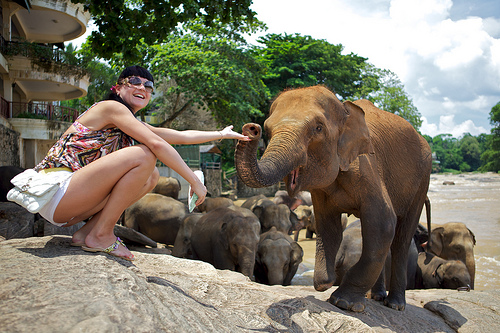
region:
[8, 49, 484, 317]
Woman getting close to an elephant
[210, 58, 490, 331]
Baby elephant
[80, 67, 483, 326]
Herd of elephants near water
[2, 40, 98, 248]
Building with a balcony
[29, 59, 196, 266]
Woman wearing sunglasses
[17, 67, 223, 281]
Woman wearing flip flops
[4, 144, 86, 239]
White purse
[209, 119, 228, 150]
Braclet on a woman's wrist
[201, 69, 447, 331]
Elephant walking on a rock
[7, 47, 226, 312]
Woman wearing white shorts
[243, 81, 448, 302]
brown elephant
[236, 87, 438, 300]
brown elephant touching young woman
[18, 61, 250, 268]
young woman touching brown elephant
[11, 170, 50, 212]
white purse worn by young woman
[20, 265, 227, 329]
gray rock by young woman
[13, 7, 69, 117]
balconies by river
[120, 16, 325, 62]
trees with green leaves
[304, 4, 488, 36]
white clouds against blue sky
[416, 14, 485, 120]
white clouds against blue sky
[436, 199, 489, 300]
brown elephants in river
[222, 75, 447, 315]
young elephant with older elephants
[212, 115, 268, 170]
hand stretched towards elephant's trunk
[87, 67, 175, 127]
woman is wearing sunglasses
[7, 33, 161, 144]
balconies of building behind woman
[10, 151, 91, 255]
matching white purse and shorts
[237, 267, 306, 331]
shadow cast of elephants trunk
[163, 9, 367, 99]
green tree tops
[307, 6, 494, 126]
big fluffy white clouds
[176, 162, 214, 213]
woman holding something in hands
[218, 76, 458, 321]
elephant playing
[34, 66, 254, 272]
a lady feeding a elephant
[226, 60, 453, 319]
an elephant eating from a lady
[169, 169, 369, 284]
a bunch of elephants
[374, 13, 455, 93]
a few clouds in the sky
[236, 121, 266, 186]
the nose of the elephant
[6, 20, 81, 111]
the building in the photo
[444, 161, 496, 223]
the river in the picture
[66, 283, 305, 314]
the rocks the lady is kneeling on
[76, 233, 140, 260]
the ladies feet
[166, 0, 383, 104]
trees that are in the photo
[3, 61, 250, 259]
Lady pausing for a picture.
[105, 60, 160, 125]
The woman is smiling.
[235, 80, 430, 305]
The elephant is walking towards the lady.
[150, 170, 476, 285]
Elephants playing in the water.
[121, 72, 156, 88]
The lady is wearing sunglasses.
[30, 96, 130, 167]
Lady wearing a light printed top.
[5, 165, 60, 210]
The woman is carrying a white purse.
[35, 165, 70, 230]
The woman is wearing a white short.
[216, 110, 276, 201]
The lady is trying to feed the elephant.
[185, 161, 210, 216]
Lady holding a bag of peanuts to feed the elephant.